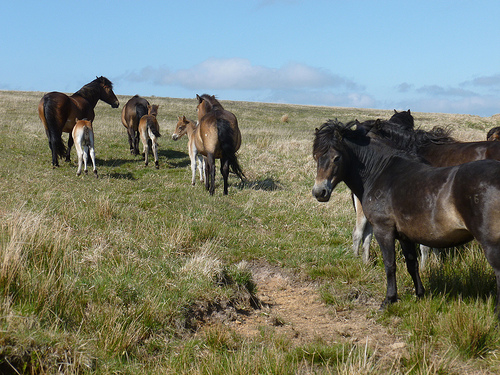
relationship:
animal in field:
[36, 75, 119, 169] [23, 199, 283, 333]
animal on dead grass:
[36, 75, 119, 169] [299, 286, 315, 321]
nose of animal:
[307, 177, 334, 205] [310, 118, 500, 310]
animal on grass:
[171, 115, 204, 186] [8, 86, 497, 373]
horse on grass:
[184, 94, 258, 194] [8, 86, 497, 373]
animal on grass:
[138, 103, 162, 169] [8, 86, 497, 373]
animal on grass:
[72, 118, 97, 178] [8, 86, 497, 373]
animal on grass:
[36, 75, 119, 169] [8, 86, 497, 373]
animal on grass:
[310, 118, 500, 310] [8, 86, 497, 373]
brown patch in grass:
[181, 264, 365, 336] [8, 86, 497, 373]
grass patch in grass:
[235, 128, 344, 209] [8, 86, 497, 373]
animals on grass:
[44, 77, 498, 320] [8, 86, 497, 373]